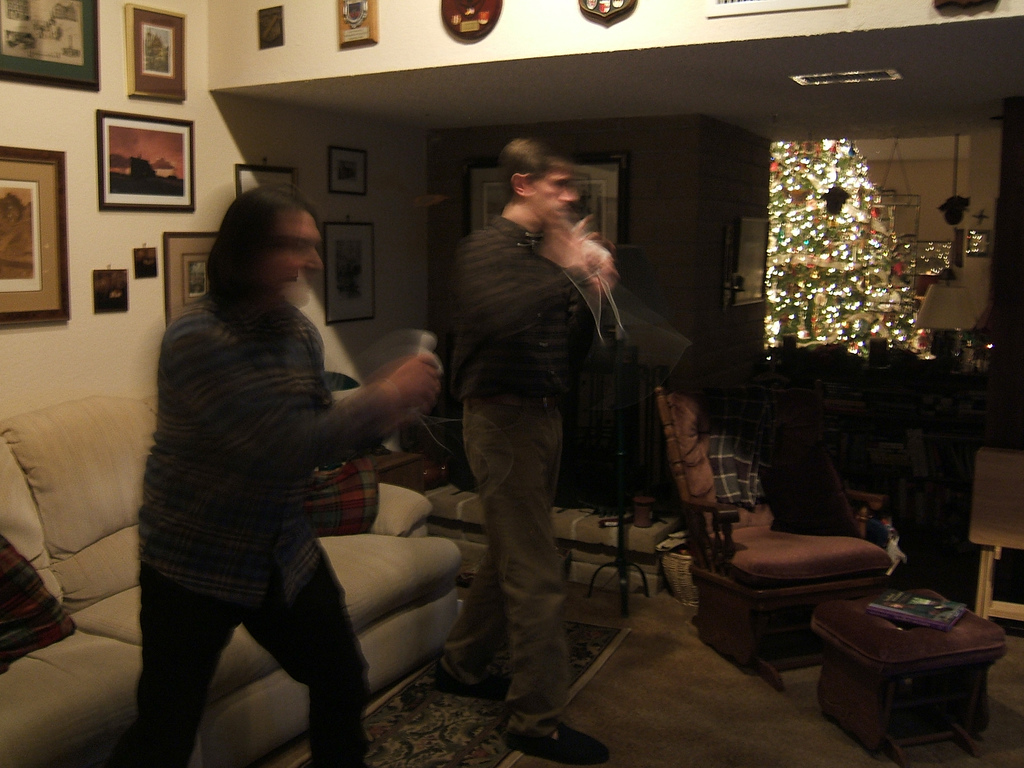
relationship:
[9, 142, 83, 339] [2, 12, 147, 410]
picture on wall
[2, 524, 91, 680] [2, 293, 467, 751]
pillow on sofa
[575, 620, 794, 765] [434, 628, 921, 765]
rug on floor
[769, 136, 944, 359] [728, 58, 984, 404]
lights on wall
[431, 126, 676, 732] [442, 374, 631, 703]
man in pants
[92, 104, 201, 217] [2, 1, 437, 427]
picture on wall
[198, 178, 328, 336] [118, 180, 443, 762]
head of a man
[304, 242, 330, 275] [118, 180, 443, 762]
nose of a man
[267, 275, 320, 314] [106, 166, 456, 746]
chin of a man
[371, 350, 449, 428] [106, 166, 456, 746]
hand of a man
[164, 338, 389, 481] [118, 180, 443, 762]
arm of a man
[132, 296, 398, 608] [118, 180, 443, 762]
shirt of a man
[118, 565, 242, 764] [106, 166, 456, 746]
leg of a man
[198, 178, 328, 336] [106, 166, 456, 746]
head of a man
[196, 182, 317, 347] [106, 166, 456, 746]
hair of a man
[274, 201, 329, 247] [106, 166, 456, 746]
forehead of a man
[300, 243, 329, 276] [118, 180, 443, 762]
nose of a man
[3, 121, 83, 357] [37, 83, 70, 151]
picture on wall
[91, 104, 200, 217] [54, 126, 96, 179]
picture on wall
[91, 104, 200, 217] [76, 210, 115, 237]
picture on wall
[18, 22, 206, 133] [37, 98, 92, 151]
picture on wall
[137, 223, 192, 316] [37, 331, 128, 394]
picture on wall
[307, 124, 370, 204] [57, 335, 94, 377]
picture on wall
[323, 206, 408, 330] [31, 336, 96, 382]
picture on wall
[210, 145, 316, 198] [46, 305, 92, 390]
picture on wall